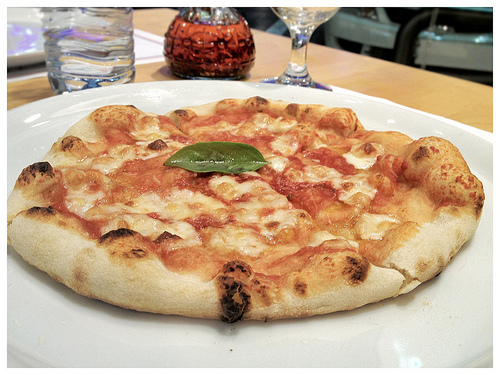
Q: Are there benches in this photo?
A: No, there are no benches.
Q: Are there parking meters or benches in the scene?
A: No, there are no benches or parking meters.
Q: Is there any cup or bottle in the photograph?
A: Yes, there is a bottle.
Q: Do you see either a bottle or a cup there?
A: Yes, there is a bottle.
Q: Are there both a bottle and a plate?
A: Yes, there are both a bottle and a plate.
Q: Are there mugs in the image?
A: No, there are no mugs.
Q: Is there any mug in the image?
A: No, there are no mugs.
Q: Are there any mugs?
A: No, there are no mugs.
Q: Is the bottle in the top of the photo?
A: Yes, the bottle is in the top of the image.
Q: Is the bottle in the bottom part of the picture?
A: No, the bottle is in the top of the image.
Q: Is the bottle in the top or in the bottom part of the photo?
A: The bottle is in the top of the image.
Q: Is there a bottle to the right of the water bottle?
A: Yes, there is a bottle to the right of the water bottle.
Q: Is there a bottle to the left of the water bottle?
A: No, the bottle is to the right of the water bottle.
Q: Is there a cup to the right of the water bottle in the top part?
A: No, there is a bottle to the right of the water bottle.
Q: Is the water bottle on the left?
A: Yes, the water bottle is on the left of the image.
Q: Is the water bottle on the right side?
A: No, the water bottle is on the left of the image.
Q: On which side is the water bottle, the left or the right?
A: The water bottle is on the left of the image.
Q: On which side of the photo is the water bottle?
A: The water bottle is on the left of the image.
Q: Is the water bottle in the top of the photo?
A: Yes, the water bottle is in the top of the image.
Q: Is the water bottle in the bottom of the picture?
A: No, the water bottle is in the top of the image.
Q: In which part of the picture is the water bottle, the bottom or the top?
A: The water bottle is in the top of the image.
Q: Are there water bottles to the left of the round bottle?
A: Yes, there is a water bottle to the left of the bottle.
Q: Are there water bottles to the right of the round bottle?
A: No, the water bottle is to the left of the bottle.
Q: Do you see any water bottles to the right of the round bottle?
A: No, the water bottle is to the left of the bottle.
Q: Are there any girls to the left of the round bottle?
A: No, there is a water bottle to the left of the bottle.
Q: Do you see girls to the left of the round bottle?
A: No, there is a water bottle to the left of the bottle.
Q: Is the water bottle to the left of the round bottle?
A: Yes, the water bottle is to the left of the bottle.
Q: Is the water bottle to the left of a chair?
A: No, the water bottle is to the left of the bottle.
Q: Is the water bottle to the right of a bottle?
A: No, the water bottle is to the left of a bottle.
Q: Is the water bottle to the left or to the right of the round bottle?
A: The water bottle is to the left of the bottle.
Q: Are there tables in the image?
A: Yes, there is a table.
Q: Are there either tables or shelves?
A: Yes, there is a table.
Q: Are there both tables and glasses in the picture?
A: Yes, there are both a table and glasses.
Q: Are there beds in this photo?
A: No, there are no beds.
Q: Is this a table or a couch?
A: This is a table.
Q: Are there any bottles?
A: Yes, there is a bottle.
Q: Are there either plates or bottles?
A: Yes, there is a bottle.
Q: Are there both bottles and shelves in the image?
A: No, there is a bottle but no shelves.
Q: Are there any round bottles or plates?
A: Yes, there is a round bottle.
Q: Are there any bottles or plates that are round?
A: Yes, the bottle is round.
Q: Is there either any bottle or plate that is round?
A: Yes, the bottle is round.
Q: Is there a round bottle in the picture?
A: Yes, there is a round bottle.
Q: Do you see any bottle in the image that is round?
A: Yes, there is a bottle that is round.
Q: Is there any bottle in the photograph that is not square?
A: Yes, there is a round bottle.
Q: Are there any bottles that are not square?
A: Yes, there is a round bottle.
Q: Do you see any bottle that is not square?
A: Yes, there is a round bottle.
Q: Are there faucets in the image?
A: No, there are no faucets.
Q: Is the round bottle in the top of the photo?
A: Yes, the bottle is in the top of the image.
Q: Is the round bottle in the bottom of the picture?
A: No, the bottle is in the top of the image.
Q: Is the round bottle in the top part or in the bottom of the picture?
A: The bottle is in the top of the image.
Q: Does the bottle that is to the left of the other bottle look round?
A: Yes, the bottle is round.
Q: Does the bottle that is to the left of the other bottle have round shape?
A: Yes, the bottle is round.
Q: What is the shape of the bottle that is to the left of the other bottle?
A: The bottle is round.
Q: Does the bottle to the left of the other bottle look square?
A: No, the bottle is round.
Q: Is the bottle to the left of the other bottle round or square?
A: The bottle is round.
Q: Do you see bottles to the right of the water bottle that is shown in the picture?
A: Yes, there is a bottle to the right of the water bottle.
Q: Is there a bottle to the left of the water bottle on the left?
A: No, the bottle is to the right of the water bottle.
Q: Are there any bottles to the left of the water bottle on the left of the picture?
A: No, the bottle is to the right of the water bottle.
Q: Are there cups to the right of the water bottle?
A: No, there is a bottle to the right of the water bottle.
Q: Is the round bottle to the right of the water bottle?
A: Yes, the bottle is to the right of the water bottle.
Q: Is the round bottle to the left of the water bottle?
A: No, the bottle is to the right of the water bottle.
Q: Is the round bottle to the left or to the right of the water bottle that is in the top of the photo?
A: The bottle is to the right of the water bottle.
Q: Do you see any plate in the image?
A: Yes, there is a plate.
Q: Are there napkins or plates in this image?
A: Yes, there is a plate.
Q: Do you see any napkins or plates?
A: Yes, there is a plate.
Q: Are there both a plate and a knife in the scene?
A: No, there is a plate but no knives.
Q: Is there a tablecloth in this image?
A: No, there are no tablecloths.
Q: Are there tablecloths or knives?
A: No, there are no tablecloths or knives.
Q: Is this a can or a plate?
A: This is a plate.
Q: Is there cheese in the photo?
A: Yes, there is cheese.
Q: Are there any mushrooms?
A: No, there are no mushrooms.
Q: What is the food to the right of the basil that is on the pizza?
A: The food is cheese.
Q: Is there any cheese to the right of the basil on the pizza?
A: Yes, there is cheese to the right of the basil.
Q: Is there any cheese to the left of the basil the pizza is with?
A: No, the cheese is to the right of the basil.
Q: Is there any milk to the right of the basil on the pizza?
A: No, there is cheese to the right of the basil.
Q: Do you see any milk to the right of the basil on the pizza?
A: No, there is cheese to the right of the basil.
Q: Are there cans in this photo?
A: No, there are no cans.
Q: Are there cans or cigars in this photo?
A: No, there are no cans or cigars.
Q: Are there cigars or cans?
A: No, there are no cans or cigars.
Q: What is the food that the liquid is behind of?
A: The food is a pizza.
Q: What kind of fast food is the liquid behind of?
A: The liquid is behind the pizza.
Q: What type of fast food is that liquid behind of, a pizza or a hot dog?
A: The liquid is behind a pizza.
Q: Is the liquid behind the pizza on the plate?
A: Yes, the liquid is behind the pizza.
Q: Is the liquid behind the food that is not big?
A: Yes, the liquid is behind the pizza.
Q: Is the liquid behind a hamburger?
A: No, the liquid is behind the pizza.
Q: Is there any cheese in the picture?
A: Yes, there is cheese.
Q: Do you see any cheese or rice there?
A: Yes, there is cheese.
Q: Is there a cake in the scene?
A: No, there are no cakes.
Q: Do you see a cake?
A: No, there are no cakes.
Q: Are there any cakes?
A: No, there are no cakes.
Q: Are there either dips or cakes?
A: No, there are no cakes or dips.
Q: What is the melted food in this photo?
A: The food is cheese.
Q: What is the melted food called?
A: The food is cheese.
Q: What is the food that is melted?
A: The food is cheese.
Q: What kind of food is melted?
A: The food is cheese.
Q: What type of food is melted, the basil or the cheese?
A: The cheese is melted.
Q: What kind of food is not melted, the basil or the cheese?
A: The basil is not melted.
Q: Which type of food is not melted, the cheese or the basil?
A: The basil is not melted.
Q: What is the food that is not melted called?
A: The food is basil.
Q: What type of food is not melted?
A: The food is basil.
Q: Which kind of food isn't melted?
A: The food is basil.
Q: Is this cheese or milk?
A: This is cheese.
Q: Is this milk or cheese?
A: This is cheese.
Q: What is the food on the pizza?
A: The food is cheese.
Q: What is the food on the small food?
A: The food is cheese.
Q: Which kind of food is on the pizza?
A: The food is cheese.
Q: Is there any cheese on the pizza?
A: Yes, there is cheese on the pizza.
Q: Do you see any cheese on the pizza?
A: Yes, there is cheese on the pizza.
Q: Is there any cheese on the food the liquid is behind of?
A: Yes, there is cheese on the pizza.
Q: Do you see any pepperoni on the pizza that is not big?
A: No, there is cheese on the pizza.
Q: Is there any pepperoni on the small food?
A: No, there is cheese on the pizza.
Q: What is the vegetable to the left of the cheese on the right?
A: The vegetable is basil.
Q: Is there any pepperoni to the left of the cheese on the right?
A: No, there is basil to the left of the cheese.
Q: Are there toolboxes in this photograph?
A: No, there are no toolboxes.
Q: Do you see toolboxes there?
A: No, there are no toolboxes.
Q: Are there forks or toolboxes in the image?
A: No, there are no toolboxes or forks.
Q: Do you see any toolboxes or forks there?
A: No, there are no toolboxes or forks.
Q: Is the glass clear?
A: Yes, the glass is clear.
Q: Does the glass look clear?
A: Yes, the glass is clear.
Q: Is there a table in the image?
A: Yes, there is a table.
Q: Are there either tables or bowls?
A: Yes, there is a table.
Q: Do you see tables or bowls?
A: Yes, there is a table.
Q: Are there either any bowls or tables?
A: Yes, there is a table.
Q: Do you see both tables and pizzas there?
A: Yes, there are both a table and a pizza.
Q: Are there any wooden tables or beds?
A: Yes, there is a wood table.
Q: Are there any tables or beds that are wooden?
A: Yes, the table is wooden.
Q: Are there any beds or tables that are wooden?
A: Yes, the table is wooden.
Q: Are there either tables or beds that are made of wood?
A: Yes, the table is made of wood.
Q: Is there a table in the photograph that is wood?
A: Yes, there is a wood table.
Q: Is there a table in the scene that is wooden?
A: Yes, there is a table that is wooden.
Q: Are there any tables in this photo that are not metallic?
A: Yes, there is a wooden table.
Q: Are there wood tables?
A: Yes, there is a table that is made of wood.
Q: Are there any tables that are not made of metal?
A: Yes, there is a table that is made of wood.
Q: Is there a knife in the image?
A: No, there are no knives.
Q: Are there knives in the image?
A: No, there are no knives.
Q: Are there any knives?
A: No, there are no knives.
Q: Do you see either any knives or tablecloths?
A: No, there are no knives or tablecloths.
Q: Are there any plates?
A: Yes, there is a plate.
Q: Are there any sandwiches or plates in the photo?
A: Yes, there is a plate.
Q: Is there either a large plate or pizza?
A: Yes, there is a large plate.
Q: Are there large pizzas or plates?
A: Yes, there is a large plate.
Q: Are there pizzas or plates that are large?
A: Yes, the plate is large.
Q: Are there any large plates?
A: Yes, there is a large plate.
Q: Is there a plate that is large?
A: Yes, there is a plate that is large.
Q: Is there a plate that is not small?
A: Yes, there is a large plate.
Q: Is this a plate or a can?
A: This is a plate.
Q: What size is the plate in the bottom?
A: The plate is large.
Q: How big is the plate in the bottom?
A: The plate is large.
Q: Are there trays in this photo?
A: No, there are no trays.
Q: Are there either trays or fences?
A: No, there are no trays or fences.